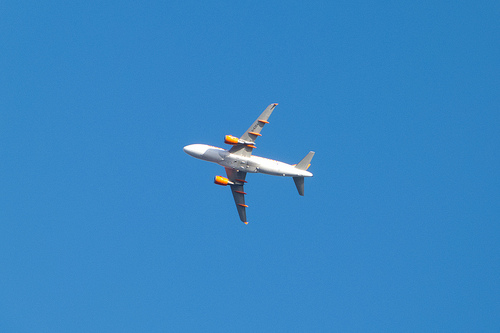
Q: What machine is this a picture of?
A: Airplane.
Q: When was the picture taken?
A: Daytime.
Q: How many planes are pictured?
A: One.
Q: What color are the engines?
A: Orange.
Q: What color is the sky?
A: Blue.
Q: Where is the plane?
A: The sky.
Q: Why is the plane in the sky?
A: Flying.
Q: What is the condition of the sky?
A: Clear.